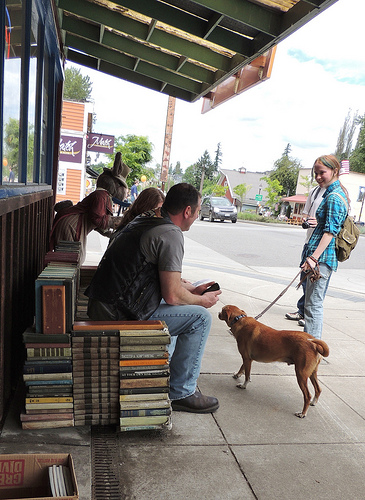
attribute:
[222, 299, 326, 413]
dog — cute, bored, short, brown, standing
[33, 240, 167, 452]
books — stacked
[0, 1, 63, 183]
window — closed, black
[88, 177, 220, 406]
man — sitting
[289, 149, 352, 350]
girl — short, white, small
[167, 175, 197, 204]
hair — black, short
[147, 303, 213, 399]
trousers — blue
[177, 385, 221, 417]
shoes — black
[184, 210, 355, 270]
street — dark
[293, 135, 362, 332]
girl — small